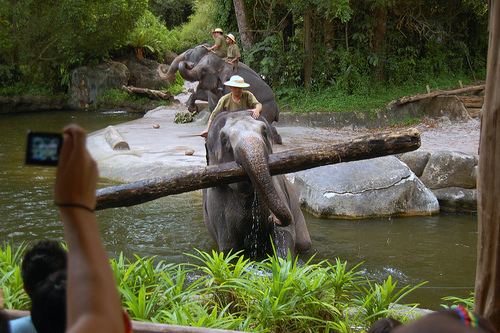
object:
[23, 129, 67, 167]
camera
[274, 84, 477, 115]
grass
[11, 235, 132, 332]
children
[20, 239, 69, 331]
hair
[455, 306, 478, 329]
ribbon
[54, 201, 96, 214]
strap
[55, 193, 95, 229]
wrist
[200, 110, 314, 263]
elephant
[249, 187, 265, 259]
water dripping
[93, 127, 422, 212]
log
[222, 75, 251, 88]
hat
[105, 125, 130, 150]
log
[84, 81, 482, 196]
cement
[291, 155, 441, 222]
rock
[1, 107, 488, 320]
water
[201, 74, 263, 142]
rider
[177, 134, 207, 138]
stick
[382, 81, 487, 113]
tree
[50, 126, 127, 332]
arm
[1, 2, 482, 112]
vegetation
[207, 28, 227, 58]
people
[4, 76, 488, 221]
bank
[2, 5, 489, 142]
background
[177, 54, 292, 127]
elephants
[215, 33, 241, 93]
riders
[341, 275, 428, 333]
plants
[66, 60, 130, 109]
boulders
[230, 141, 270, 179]
mouth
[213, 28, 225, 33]
hats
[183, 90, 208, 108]
legs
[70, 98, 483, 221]
ground